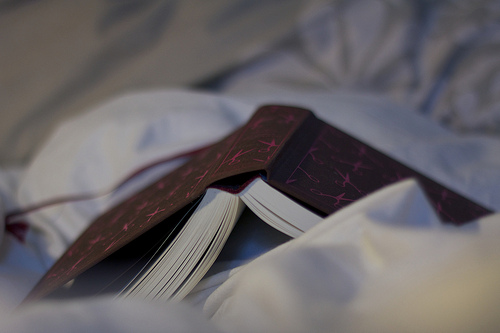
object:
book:
[10, 103, 497, 317]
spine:
[203, 103, 313, 195]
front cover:
[11, 103, 262, 313]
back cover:
[266, 114, 498, 227]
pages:
[175, 196, 239, 308]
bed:
[0, 0, 497, 333]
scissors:
[257, 135, 282, 154]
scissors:
[309, 188, 357, 209]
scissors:
[333, 166, 367, 196]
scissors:
[329, 155, 375, 176]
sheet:
[1, 177, 500, 333]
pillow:
[18, 51, 500, 263]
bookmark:
[0, 142, 220, 245]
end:
[4, 217, 31, 245]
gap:
[205, 169, 268, 194]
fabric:
[0, 0, 498, 333]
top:
[16, 169, 330, 313]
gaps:
[245, 194, 305, 235]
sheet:
[0, 0, 500, 170]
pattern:
[138, 204, 167, 231]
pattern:
[298, 164, 320, 186]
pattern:
[218, 142, 257, 167]